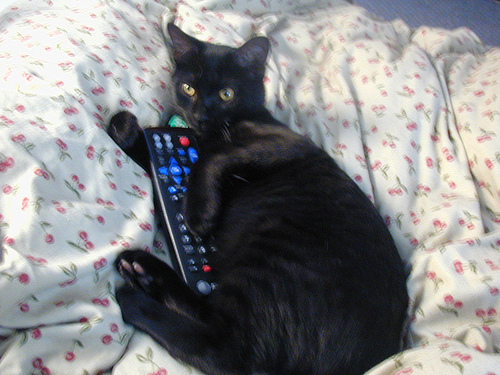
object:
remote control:
[140, 126, 225, 304]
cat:
[105, 22, 409, 374]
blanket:
[2, 1, 498, 372]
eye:
[217, 87, 236, 103]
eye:
[180, 80, 196, 97]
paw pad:
[134, 262, 142, 275]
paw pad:
[122, 259, 134, 275]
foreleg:
[190, 132, 312, 238]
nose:
[193, 109, 210, 124]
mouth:
[191, 121, 208, 135]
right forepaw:
[109, 110, 140, 153]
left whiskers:
[220, 119, 233, 144]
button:
[179, 136, 192, 147]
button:
[169, 165, 183, 179]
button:
[188, 147, 199, 166]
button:
[177, 147, 187, 159]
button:
[168, 186, 178, 196]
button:
[159, 166, 171, 174]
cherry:
[91, 86, 105, 100]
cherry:
[101, 69, 113, 77]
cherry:
[78, 98, 87, 106]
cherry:
[62, 107, 78, 116]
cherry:
[69, 53, 79, 59]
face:
[169, 56, 250, 139]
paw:
[184, 179, 220, 240]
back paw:
[115, 283, 158, 322]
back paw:
[113, 250, 167, 294]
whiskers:
[162, 99, 188, 120]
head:
[163, 23, 271, 145]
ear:
[235, 36, 270, 77]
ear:
[166, 22, 199, 57]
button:
[196, 279, 215, 295]